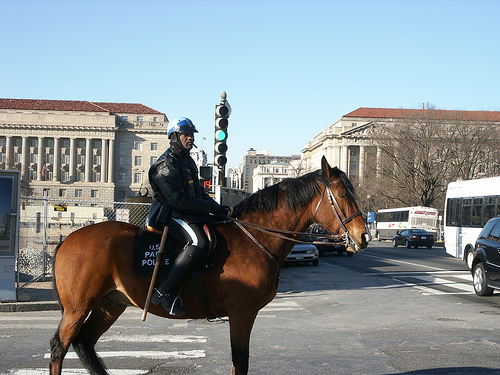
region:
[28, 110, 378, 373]
Police officer on a horse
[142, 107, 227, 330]
Police officer wearing a helmet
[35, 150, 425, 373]
Brown colored horse with black mane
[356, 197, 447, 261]
Car beside city bus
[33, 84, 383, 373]
Police officer on horse beside traffic signal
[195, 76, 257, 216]
Traffic signal with one brightly lit light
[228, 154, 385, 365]
Horse wearing a bridle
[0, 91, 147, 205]
Large building with columns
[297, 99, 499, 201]
Building with red roof top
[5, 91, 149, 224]
Building with nearby fence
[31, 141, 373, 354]
the horse is brown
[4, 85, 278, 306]
the horse is brown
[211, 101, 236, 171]
the strret light has turned green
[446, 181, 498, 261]
their is a bus in the street that is the color white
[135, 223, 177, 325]
the policeman has a nightstick on his waist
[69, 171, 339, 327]
the horse is the color brown and black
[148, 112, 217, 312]
a policeman is mounted upon the horse in the street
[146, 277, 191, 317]
the man is wearing black colored boots on his feet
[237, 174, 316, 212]
the horse has a blck mane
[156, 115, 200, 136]
the man is wearing a blue and white helmet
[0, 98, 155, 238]
the building in the background is light beige with a red colored roof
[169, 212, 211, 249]
the policeman is wearing black pants with a white strie on the side of leg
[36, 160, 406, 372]
A brown horse on street.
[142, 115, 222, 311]
A policeman on a horse.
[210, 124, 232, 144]
A green traffic light.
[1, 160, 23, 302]
A sign box on sidewalk.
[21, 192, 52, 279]
A chain link fence.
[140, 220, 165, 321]
A brown police baton.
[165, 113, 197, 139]
A blue and white police helmet.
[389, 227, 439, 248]
A black car on street.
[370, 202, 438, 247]
A white bus with red stripe on back.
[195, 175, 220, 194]
A cross walk timer sign.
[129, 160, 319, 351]
the horse is brown